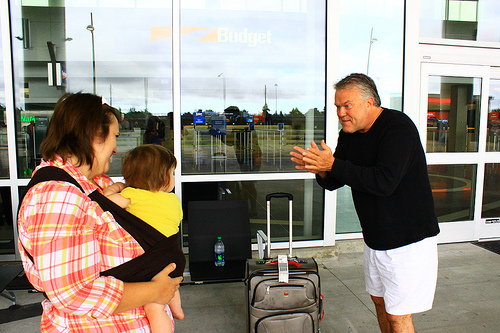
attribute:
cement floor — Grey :
[4, 239, 499, 325]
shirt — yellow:
[122, 184, 184, 235]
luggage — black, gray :
[241, 257, 329, 331]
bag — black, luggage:
[180, 174, 260, 286]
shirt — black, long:
[314, 107, 446, 254]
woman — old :
[18, 90, 182, 331]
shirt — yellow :
[115, 172, 221, 250]